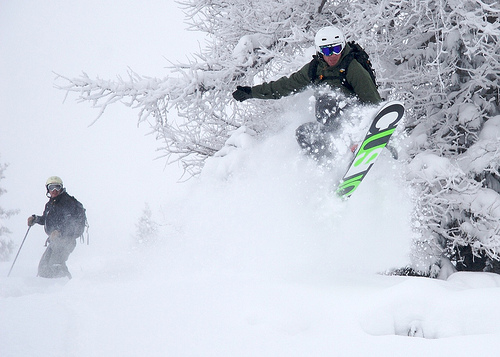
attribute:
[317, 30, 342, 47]
helmet — white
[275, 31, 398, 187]
man — in air, performing trick, snowboarding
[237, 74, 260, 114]
gloves — green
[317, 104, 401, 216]
board — green, custom-designed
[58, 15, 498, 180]
tree — large, snow-covered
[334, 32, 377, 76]
backpack — black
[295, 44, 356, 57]
goggles — white, blue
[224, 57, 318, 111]
arm — stretched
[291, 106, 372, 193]
snow — flying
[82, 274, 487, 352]
ground — snow-covered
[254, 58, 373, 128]
jacket — green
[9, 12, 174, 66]
sky — overcast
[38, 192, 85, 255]
coat — black